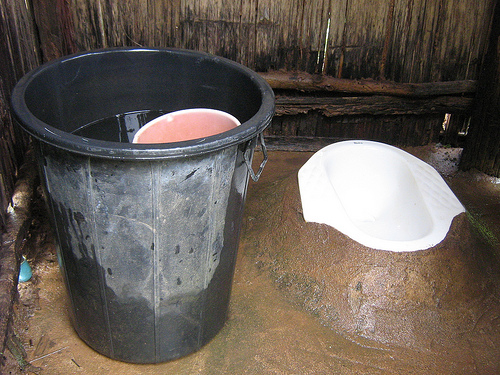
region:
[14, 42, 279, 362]
the bucket is black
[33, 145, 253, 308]
white color on bucket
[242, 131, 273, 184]
black handle on bucket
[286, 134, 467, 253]
white hole in ground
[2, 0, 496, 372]
wall is made of wood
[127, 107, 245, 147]
white object in bucket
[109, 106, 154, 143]
reflection in the bucket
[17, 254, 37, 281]
blue object on ground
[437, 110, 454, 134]
hole in the wall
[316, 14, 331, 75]
cracks in the wood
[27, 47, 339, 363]
a garbage can outisde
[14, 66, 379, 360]
a trash can outside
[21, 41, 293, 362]
a black garabage can outside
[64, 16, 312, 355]
a black garbage can outside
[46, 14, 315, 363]
a large garbage can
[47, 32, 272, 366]
a large trash can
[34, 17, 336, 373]
a large black garbage can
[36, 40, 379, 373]
a large black trash can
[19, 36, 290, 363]
a garbage can that is black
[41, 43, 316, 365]
a trash can that is large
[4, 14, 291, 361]
black bucket with water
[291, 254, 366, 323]
wet stone brown and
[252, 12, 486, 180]
rotten wood from water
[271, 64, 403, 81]
rotten wood from water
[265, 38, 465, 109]
rotten wood from water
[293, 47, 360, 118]
rotten wood from water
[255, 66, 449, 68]
rotten wood from water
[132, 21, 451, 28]
rotten wood from water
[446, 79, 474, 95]
rotten wood from water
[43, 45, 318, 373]
a trash can outside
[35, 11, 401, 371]
a garabge can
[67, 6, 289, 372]
a trash can outside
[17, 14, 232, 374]
a large garbage can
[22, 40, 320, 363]
a large trash can outside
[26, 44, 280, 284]
a black garbage can outside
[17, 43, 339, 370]
a black trash can outside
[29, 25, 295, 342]
a large black garbage can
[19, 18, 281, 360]
a large black trash can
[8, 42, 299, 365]
black bucket on the floor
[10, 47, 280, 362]
bucket on the floor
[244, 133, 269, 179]
handle on the bucket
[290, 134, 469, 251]
lid on the floor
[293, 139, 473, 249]
lid next to bucket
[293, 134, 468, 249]
white lid next to bucket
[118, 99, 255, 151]
item in the bucket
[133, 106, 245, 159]
item in the black bucket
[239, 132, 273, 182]
handle on the black bucket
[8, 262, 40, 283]
blue item next to bucket